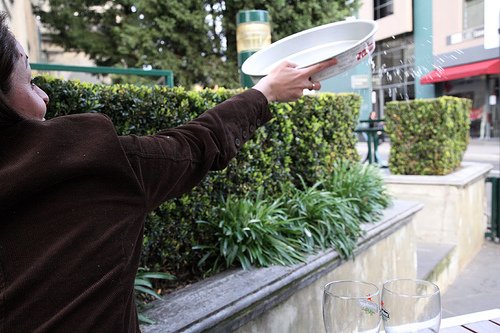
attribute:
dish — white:
[271, 39, 388, 89]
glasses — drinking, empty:
[300, 278, 411, 327]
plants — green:
[145, 73, 368, 223]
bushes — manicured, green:
[127, 101, 312, 234]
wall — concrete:
[221, 270, 331, 324]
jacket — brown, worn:
[44, 141, 207, 333]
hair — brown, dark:
[2, 27, 38, 73]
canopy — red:
[410, 57, 493, 90]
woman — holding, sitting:
[45, 88, 239, 289]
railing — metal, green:
[58, 64, 183, 79]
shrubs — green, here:
[204, 159, 341, 247]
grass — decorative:
[405, 109, 477, 175]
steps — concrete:
[405, 205, 491, 299]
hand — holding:
[286, 84, 324, 125]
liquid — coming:
[375, 31, 448, 102]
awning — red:
[397, 46, 499, 122]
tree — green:
[108, 10, 173, 58]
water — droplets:
[425, 34, 468, 100]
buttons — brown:
[226, 113, 273, 144]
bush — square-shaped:
[378, 93, 459, 146]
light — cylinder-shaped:
[231, 12, 269, 51]